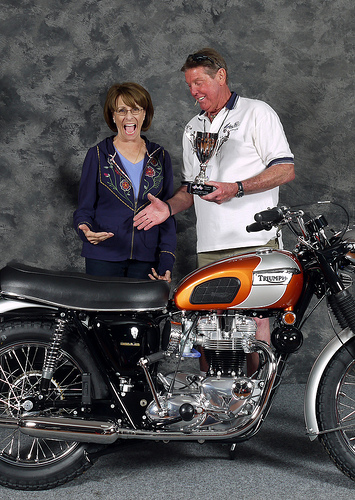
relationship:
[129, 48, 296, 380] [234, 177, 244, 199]
man wearing watch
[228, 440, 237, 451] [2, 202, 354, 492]
kickstand on motorcycle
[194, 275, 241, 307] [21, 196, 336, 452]
black on bike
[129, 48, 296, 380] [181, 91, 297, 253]
man with shirt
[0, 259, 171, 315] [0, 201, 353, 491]
black seat on bike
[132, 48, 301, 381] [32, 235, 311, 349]
man next to motorcycle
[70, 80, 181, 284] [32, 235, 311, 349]
lady next to motorcycle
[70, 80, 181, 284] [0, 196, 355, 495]
lady with bike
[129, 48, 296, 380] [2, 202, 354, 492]
man next to motorcycle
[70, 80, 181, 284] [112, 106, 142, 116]
lady wearing glasses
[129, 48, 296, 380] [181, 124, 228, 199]
man holding trophy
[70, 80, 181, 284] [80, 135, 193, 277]
lady wearing jacket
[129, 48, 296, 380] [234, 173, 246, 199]
man wearing watch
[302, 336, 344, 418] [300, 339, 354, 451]
fender on wheel